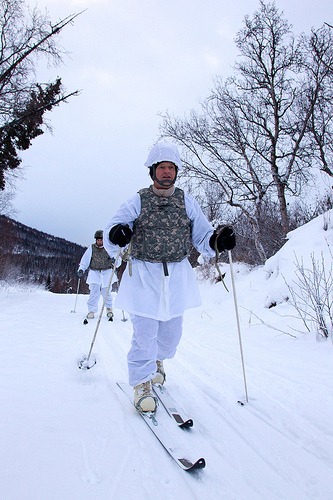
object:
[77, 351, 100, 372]
bottom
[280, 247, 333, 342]
branches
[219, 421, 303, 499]
trail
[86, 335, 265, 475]
path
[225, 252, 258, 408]
skipole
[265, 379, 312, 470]
ground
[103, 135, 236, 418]
man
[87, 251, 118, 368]
pole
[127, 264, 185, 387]
jeans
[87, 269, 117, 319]
jeans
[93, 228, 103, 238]
helmet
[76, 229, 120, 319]
man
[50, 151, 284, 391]
out front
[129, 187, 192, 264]
camo vest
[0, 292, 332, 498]
snow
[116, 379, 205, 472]
ski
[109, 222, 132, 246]
glove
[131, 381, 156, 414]
shoe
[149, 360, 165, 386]
shoe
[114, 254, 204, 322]
white pants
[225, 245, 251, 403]
pole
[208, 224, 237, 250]
glove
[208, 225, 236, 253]
hand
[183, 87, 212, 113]
wall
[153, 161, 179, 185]
face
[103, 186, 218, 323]
shirt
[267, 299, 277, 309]
hole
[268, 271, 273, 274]
hole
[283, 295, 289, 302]
hole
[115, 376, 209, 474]
skis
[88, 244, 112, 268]
vest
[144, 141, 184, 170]
cover